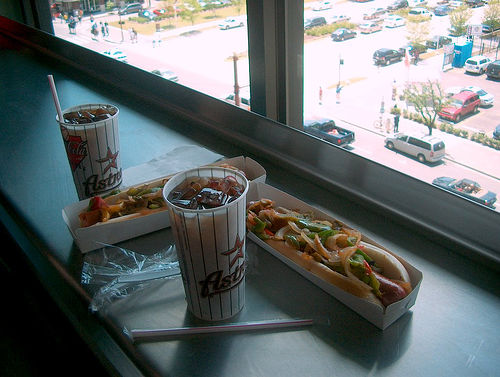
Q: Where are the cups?
A: On the counter?.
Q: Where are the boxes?
A: Next to the cups.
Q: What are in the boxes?
A: Hot dogs.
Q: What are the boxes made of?
A: Cardboard.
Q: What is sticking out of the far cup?
A: A straw.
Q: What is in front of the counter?
A: A window.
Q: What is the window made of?
A: Glass.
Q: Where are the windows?
A: In front of the counter.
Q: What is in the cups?
A: Soft drinks and ice.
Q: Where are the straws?
A: One in the cup, one on the counter.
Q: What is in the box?
A: A hot dog with toppings.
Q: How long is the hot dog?
A: A footlong.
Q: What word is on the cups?
A: Astros.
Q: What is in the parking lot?
A: Cars.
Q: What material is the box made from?
A: Paper.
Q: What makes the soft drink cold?
A: Ice.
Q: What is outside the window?
A: A parking lot.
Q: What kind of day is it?
A: Sunny.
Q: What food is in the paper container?
A: Hot dog.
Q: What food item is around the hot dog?
A: A bun.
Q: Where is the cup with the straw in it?
A: On the windowsill.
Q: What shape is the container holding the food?
A: Rectangular.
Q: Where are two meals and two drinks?
A: On a counter.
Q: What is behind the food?
A: Window.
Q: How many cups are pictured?
A: Two.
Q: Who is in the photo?
A: No one.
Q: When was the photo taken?
A: Afternoon.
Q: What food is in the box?
A: Hot Dogs.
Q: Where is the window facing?
A: A parking space.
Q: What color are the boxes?
A: White.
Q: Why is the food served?
A: To be eaten.